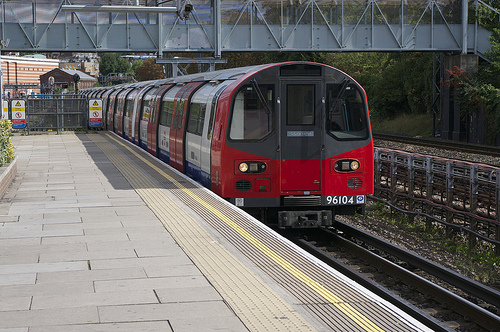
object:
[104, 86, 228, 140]
reflection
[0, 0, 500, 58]
walkway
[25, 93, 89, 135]
metal fence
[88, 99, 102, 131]
sign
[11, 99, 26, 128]
sign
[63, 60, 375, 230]
train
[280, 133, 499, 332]
tracks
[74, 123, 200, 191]
shadow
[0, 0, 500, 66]
metal structure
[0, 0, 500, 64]
bridge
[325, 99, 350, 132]
driver seat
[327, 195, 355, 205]
numbers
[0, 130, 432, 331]
ground